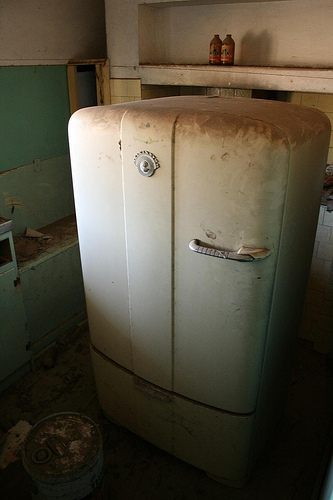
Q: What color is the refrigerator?
A: White.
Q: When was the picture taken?
A: Daytime.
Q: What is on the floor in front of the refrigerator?
A: Canister.